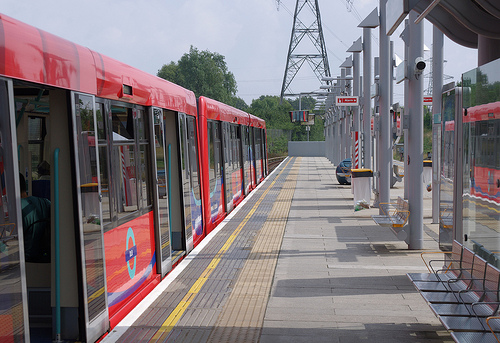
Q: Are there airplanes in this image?
A: No, there are no airplanes.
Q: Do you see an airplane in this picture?
A: No, there are no airplanes.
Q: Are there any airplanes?
A: No, there are no airplanes.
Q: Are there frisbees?
A: No, there are no frisbees.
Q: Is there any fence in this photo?
A: No, there are no fences.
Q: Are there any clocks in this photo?
A: No, there are no clocks.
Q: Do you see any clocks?
A: No, there are no clocks.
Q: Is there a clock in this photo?
A: No, there are no clocks.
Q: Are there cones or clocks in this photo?
A: No, there are no clocks or cones.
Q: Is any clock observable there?
A: No, there are no clocks.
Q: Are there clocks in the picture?
A: No, there are no clocks.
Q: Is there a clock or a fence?
A: No, there are no clocks or fences.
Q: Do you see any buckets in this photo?
A: No, there are no buckets.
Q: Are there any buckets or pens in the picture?
A: No, there are no buckets or pens.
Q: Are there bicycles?
A: No, there are no bicycles.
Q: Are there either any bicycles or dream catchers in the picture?
A: No, there are no bicycles or dream catchers.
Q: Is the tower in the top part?
A: Yes, the tower is in the top of the image.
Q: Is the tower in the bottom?
A: No, the tower is in the top of the image.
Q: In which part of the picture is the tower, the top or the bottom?
A: The tower is in the top of the image.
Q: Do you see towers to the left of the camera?
A: Yes, there is a tower to the left of the camera.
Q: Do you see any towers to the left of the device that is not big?
A: Yes, there is a tower to the left of the camera.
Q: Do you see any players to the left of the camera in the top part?
A: No, there is a tower to the left of the camera.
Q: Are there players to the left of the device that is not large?
A: No, there is a tower to the left of the camera.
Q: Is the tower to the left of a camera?
A: Yes, the tower is to the left of a camera.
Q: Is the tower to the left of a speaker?
A: No, the tower is to the left of a camera.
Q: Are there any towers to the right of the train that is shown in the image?
A: Yes, there is a tower to the right of the train.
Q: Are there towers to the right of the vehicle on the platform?
A: Yes, there is a tower to the right of the train.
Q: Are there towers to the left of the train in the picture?
A: No, the tower is to the right of the train.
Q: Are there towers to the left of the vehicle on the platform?
A: No, the tower is to the right of the train.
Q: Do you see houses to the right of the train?
A: No, there is a tower to the right of the train.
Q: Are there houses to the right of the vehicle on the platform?
A: No, there is a tower to the right of the train.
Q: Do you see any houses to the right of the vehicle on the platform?
A: No, there is a tower to the right of the train.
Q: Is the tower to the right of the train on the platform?
A: Yes, the tower is to the right of the train.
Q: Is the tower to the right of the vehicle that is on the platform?
A: Yes, the tower is to the right of the train.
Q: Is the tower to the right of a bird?
A: No, the tower is to the right of the train.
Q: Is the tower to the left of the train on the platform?
A: No, the tower is to the right of the train.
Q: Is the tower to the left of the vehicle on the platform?
A: No, the tower is to the right of the train.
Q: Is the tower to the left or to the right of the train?
A: The tower is to the right of the train.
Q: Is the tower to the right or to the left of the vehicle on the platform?
A: The tower is to the right of the train.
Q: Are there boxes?
A: No, there are no boxes.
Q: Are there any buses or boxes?
A: No, there are no boxes or buses.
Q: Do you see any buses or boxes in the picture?
A: No, there are no boxes or buses.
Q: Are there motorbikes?
A: No, there are no motorbikes.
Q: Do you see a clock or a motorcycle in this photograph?
A: No, there are no motorcycles or clocks.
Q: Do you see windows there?
A: Yes, there is a window.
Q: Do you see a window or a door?
A: Yes, there is a window.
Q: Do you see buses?
A: No, there are no buses.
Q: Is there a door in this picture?
A: Yes, there is a door.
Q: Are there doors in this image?
A: Yes, there is a door.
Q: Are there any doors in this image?
A: Yes, there is a door.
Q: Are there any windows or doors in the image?
A: Yes, there is a door.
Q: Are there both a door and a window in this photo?
A: Yes, there are both a door and a window.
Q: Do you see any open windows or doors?
A: Yes, there is an open door.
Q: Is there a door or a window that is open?
A: Yes, the door is open.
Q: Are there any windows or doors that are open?
A: Yes, the door is open.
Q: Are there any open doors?
A: Yes, there is an open door.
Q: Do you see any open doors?
A: Yes, there is an open door.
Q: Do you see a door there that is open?
A: Yes, there is a door that is open.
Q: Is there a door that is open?
A: Yes, there is a door that is open.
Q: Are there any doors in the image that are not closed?
A: Yes, there is a open door.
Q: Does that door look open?
A: Yes, the door is open.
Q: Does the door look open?
A: Yes, the door is open.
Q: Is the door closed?
A: No, the door is open.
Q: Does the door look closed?
A: No, the door is open.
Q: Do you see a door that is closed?
A: No, there is a door but it is open.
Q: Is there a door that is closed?
A: No, there is a door but it is open.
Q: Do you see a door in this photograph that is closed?
A: No, there is a door but it is open.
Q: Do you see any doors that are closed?
A: No, there is a door but it is open.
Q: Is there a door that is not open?
A: No, there is a door but it is open.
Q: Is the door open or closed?
A: The door is open.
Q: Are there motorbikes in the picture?
A: No, there are no motorbikes.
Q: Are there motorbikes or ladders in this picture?
A: No, there are no motorbikes or ladders.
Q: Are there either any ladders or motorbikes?
A: No, there are no motorbikes or ladders.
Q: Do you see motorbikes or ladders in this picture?
A: No, there are no motorbikes or ladders.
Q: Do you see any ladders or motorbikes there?
A: No, there are no motorbikes or ladders.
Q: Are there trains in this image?
A: Yes, there is a train.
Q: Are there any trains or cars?
A: Yes, there is a train.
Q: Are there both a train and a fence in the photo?
A: No, there is a train but no fences.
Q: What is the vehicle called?
A: The vehicle is a train.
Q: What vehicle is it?
A: The vehicle is a train.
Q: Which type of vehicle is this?
A: That is a train.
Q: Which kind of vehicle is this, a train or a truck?
A: That is a train.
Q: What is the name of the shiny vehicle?
A: The vehicle is a train.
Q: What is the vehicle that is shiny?
A: The vehicle is a train.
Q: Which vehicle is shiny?
A: The vehicle is a train.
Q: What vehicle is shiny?
A: The vehicle is a train.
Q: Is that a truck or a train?
A: That is a train.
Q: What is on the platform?
A: The train is on the platform.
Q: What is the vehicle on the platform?
A: The vehicle is a train.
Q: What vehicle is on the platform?
A: The vehicle is a train.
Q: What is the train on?
A: The train is on the platform.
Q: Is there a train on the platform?
A: Yes, there is a train on the platform.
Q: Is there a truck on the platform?
A: No, there is a train on the platform.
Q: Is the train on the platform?
A: Yes, the train is on the platform.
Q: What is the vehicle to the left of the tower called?
A: The vehicle is a train.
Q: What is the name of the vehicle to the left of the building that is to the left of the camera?
A: The vehicle is a train.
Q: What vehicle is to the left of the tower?
A: The vehicle is a train.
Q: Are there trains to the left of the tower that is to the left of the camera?
A: Yes, there is a train to the left of the tower.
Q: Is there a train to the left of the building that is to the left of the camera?
A: Yes, there is a train to the left of the tower.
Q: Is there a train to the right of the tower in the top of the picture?
A: No, the train is to the left of the tower.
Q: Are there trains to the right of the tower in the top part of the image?
A: No, the train is to the left of the tower.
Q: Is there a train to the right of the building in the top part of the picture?
A: No, the train is to the left of the tower.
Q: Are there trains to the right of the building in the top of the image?
A: No, the train is to the left of the tower.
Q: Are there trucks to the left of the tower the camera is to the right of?
A: No, there is a train to the left of the tower.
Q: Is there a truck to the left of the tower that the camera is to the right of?
A: No, there is a train to the left of the tower.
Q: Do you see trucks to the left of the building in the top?
A: No, there is a train to the left of the tower.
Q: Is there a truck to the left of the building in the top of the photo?
A: No, there is a train to the left of the tower.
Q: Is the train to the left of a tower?
A: Yes, the train is to the left of a tower.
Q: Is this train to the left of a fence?
A: No, the train is to the left of a tower.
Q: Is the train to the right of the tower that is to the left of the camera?
A: No, the train is to the left of the tower.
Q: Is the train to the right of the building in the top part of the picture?
A: No, the train is to the left of the tower.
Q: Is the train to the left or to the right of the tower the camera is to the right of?
A: The train is to the left of the tower.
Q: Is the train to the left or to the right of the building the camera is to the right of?
A: The train is to the left of the tower.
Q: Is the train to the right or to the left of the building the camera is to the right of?
A: The train is to the left of the tower.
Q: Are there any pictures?
A: No, there are no pictures.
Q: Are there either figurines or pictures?
A: No, there are no pictures or figurines.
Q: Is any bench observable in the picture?
A: Yes, there is a bench.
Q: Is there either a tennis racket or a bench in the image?
A: Yes, there is a bench.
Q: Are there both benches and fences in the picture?
A: No, there is a bench but no fences.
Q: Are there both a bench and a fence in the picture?
A: No, there is a bench but no fences.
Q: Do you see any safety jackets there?
A: No, there are no safety jackets.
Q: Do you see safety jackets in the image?
A: No, there are no safety jackets.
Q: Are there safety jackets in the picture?
A: No, there are no safety jackets.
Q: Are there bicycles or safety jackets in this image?
A: No, there are no safety jackets or bicycles.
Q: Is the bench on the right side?
A: Yes, the bench is on the right of the image.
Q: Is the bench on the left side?
A: No, the bench is on the right of the image.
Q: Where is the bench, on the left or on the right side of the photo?
A: The bench is on the right of the image.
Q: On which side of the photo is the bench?
A: The bench is on the right of the image.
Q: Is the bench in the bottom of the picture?
A: Yes, the bench is in the bottom of the image.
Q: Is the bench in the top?
A: No, the bench is in the bottom of the image.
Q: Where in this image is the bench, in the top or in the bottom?
A: The bench is in the bottom of the image.